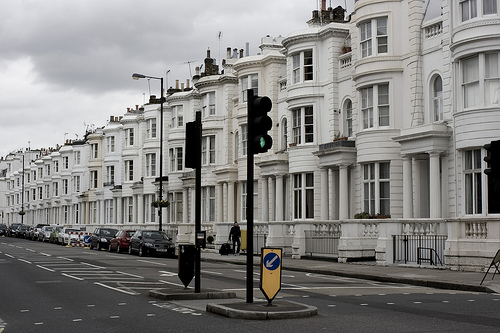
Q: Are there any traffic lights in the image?
A: Yes, there is a traffic light.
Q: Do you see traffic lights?
A: Yes, there is a traffic light.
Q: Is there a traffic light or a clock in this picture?
A: Yes, there is a traffic light.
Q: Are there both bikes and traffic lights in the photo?
A: No, there is a traffic light but no bikes.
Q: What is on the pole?
A: The traffic light is on the pole.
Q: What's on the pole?
A: The traffic light is on the pole.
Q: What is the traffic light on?
A: The traffic light is on the pole.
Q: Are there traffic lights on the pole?
A: Yes, there is a traffic light on the pole.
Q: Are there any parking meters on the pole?
A: No, there is a traffic light on the pole.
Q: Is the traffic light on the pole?
A: Yes, the traffic light is on the pole.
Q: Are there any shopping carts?
A: No, there are no shopping carts.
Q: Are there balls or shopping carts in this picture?
A: No, there are no shopping carts or balls.